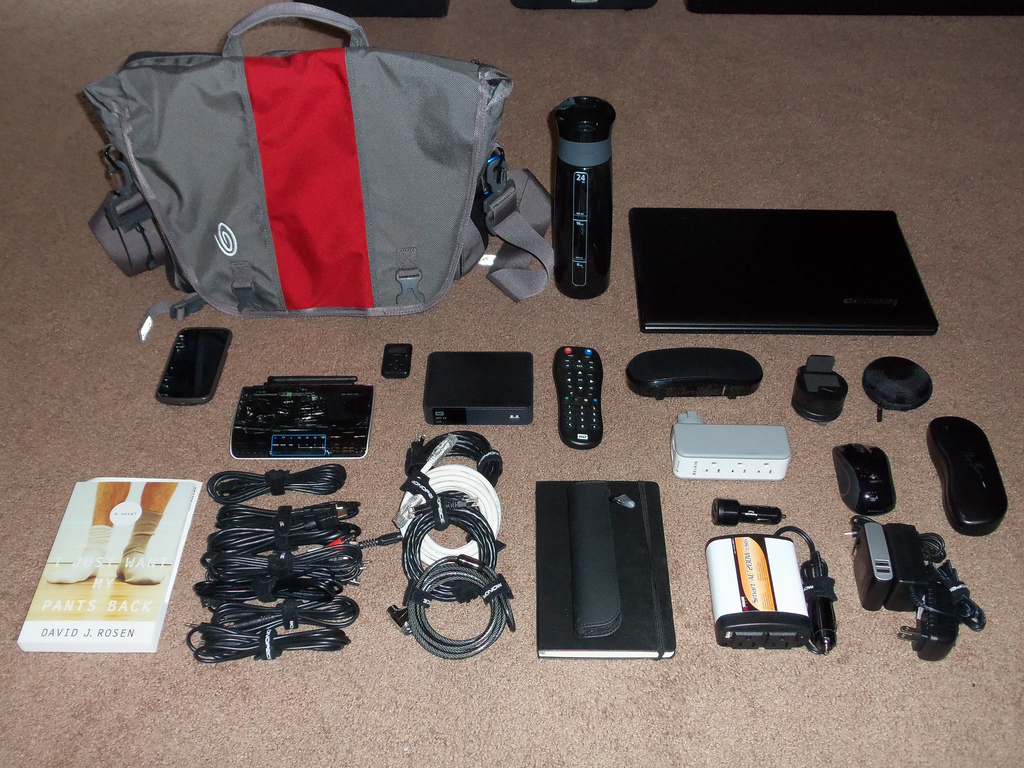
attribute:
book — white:
[15, 475, 200, 653]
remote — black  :
[547, 342, 604, 454]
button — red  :
[552, 343, 579, 360]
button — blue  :
[579, 342, 596, 359]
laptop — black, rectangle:
[623, 204, 940, 335]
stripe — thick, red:
[241, 49, 375, 316]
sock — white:
[54, 523, 111, 585]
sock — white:
[114, 509, 169, 590]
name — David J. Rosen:
[35, 624, 137, 637]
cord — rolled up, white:
[398, 435, 503, 563]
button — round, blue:
[582, 342, 596, 358]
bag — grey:
[75, 7, 562, 330]